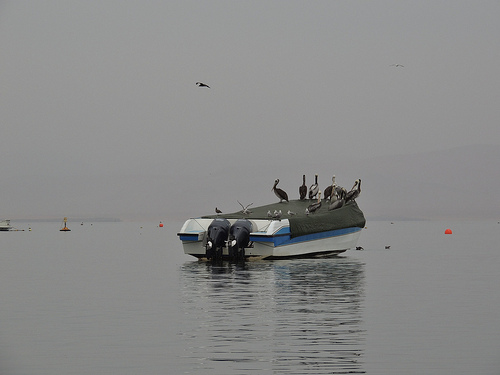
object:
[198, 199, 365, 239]
fog-covered hill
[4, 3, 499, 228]
clouds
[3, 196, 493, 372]
water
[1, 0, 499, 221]
haze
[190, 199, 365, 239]
tarp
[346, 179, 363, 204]
pelican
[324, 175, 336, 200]
pelican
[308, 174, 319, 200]
pelican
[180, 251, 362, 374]
reflection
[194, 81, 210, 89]
bird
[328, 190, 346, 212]
pelicans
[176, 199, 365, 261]
boat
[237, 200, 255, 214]
seagulls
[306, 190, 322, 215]
birds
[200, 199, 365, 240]
cover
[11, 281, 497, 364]
surface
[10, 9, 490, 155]
air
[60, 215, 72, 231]
buoy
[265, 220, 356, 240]
stripe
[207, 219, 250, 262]
motor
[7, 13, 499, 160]
sky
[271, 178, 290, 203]
bird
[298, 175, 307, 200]
bird